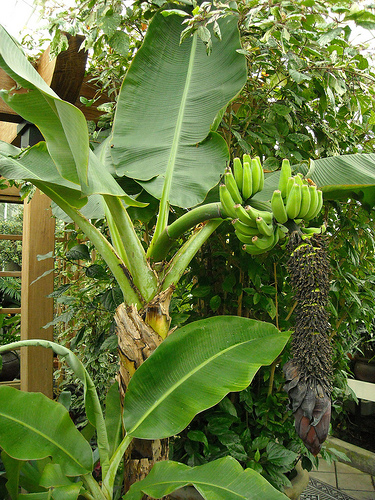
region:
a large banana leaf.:
[101, 5, 248, 209]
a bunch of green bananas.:
[214, 150, 328, 269]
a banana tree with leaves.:
[112, 282, 203, 479]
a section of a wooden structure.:
[12, 27, 94, 420]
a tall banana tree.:
[280, 196, 336, 460]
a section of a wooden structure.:
[342, 368, 373, 404]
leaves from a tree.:
[150, 0, 243, 63]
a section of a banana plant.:
[231, 255, 270, 319]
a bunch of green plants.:
[0, 300, 40, 353]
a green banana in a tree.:
[276, 152, 298, 195]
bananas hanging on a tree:
[215, 150, 323, 256]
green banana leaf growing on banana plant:
[115, 309, 289, 437]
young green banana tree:
[0, 300, 292, 495]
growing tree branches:
[245, 0, 369, 150]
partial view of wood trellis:
[0, 19, 115, 388]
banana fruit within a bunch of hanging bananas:
[240, 159, 252, 195]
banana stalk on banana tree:
[105, 190, 177, 363]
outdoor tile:
[308, 446, 371, 496]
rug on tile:
[296, 472, 352, 496]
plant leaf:
[265, 444, 301, 470]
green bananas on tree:
[203, 139, 341, 257]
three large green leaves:
[0, 310, 314, 485]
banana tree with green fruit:
[29, 18, 372, 487]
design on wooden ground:
[307, 459, 338, 497]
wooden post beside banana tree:
[8, 163, 59, 409]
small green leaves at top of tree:
[119, 0, 367, 158]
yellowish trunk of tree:
[116, 286, 189, 463]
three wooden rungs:
[0, 226, 30, 314]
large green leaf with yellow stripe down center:
[62, 307, 287, 491]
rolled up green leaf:
[9, 324, 118, 478]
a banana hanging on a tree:
[270, 188, 288, 224]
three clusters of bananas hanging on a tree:
[216, 154, 324, 256]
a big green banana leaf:
[125, 313, 294, 437]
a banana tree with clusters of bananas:
[2, 0, 373, 499]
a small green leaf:
[158, 6, 192, 21]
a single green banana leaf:
[0, 384, 94, 474]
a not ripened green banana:
[267, 191, 289, 226]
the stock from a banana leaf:
[98, 436, 129, 498]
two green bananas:
[247, 215, 277, 250]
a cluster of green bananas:
[273, 158, 322, 225]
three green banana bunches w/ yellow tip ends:
[215, 150, 326, 258]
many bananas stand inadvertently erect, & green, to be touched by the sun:
[206, 152, 325, 217]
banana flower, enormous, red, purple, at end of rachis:
[281, 363, 339, 459]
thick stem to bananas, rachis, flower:
[161, 198, 339, 239]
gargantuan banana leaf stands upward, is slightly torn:
[104, 75, 249, 211]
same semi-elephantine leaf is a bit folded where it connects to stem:
[105, 142, 198, 203]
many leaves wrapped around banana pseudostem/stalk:
[98, 275, 173, 489]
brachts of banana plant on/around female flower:
[273, 369, 328, 449]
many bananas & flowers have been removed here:
[281, 232, 334, 388]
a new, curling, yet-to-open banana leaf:
[0, 330, 111, 474]